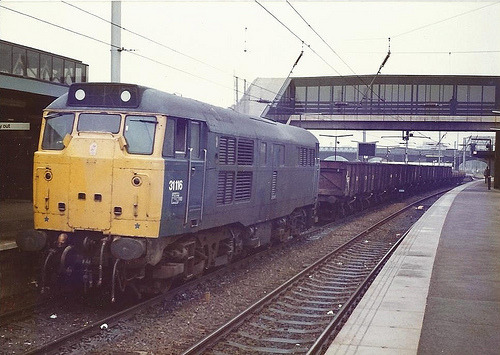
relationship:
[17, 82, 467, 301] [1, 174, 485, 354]
train on tracks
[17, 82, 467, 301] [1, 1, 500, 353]
train at station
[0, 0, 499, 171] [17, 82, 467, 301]
cables above train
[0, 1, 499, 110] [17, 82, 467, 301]
sky above train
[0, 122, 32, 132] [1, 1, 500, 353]
sign at station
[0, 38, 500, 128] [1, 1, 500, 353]
windows at station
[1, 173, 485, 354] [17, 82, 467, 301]
gravel near train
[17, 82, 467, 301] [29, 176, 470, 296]
train has wheels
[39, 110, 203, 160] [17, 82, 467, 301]
windows on train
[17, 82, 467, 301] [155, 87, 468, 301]
train has a side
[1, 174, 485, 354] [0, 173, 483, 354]
tracks made of steel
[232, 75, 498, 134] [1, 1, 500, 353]
bridge at station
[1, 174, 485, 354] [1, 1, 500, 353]
tracks at station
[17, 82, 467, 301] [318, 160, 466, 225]
train pulling cars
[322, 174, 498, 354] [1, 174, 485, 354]
walkway near tracks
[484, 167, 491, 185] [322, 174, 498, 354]
person on walkway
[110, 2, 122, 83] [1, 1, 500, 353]
pole at station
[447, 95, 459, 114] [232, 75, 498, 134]
person on bridge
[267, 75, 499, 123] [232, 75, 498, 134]
windows on bridge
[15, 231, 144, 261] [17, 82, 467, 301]
oval bumpers on train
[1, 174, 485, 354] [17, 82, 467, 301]
tracks under train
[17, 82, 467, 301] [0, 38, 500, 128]
train has windows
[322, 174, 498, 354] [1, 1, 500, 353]
walkway at station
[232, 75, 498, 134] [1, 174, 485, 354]
bridge above tracks